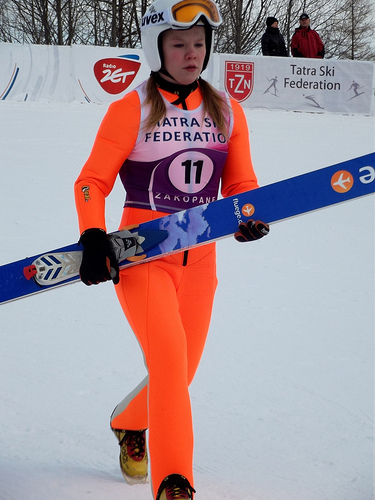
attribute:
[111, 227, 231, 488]
pants — orange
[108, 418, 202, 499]
shoes — yellow, orange, black, red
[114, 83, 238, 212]
shirt — purple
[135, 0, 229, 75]
helmet — white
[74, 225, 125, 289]
glove — black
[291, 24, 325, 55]
jacket — red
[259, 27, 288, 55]
jacket — black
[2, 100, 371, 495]
snow — white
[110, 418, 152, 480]
shoe — brown, yellow, red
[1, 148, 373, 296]
board — blue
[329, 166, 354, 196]
circle — orange